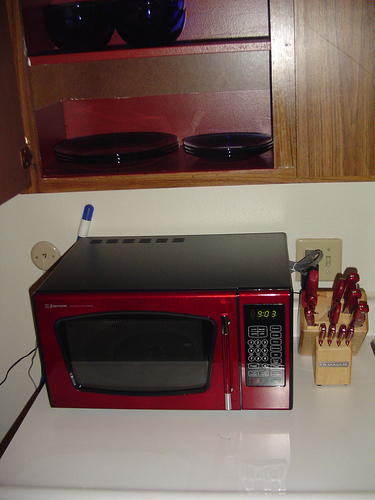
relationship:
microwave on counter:
[30, 235, 293, 411] [2, 339, 371, 496]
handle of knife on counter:
[351, 306, 369, 329] [2, 339, 371, 496]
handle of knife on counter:
[332, 302, 342, 329] [2, 339, 371, 496]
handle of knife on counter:
[332, 275, 345, 308] [2, 339, 371, 496]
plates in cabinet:
[56, 130, 273, 167] [0, 1, 373, 194]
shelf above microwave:
[30, 171, 272, 194] [30, 235, 293, 411]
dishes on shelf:
[43, 0, 184, 48] [30, 37, 271, 68]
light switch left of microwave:
[294, 239, 343, 282] [30, 235, 293, 411]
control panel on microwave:
[248, 323, 282, 379] [30, 235, 293, 411]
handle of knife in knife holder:
[351, 306, 369, 329] [301, 291, 368, 386]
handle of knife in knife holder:
[332, 302, 342, 329] [301, 291, 368, 386]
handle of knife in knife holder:
[332, 275, 345, 308] [301, 291, 368, 386]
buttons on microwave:
[246, 325, 282, 383] [30, 235, 293, 411]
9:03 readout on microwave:
[256, 309, 277, 319] [30, 235, 293, 411]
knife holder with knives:
[301, 291, 368, 386] [305, 267, 367, 345]